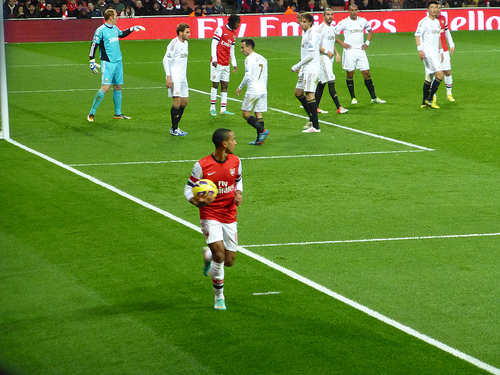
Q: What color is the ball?
A: Yellow.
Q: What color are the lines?
A: White.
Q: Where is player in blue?
A: On the left.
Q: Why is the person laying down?
A: No one laying down.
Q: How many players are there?
A: Ten.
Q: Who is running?
A: Person with ball.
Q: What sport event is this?
A: Soccer.